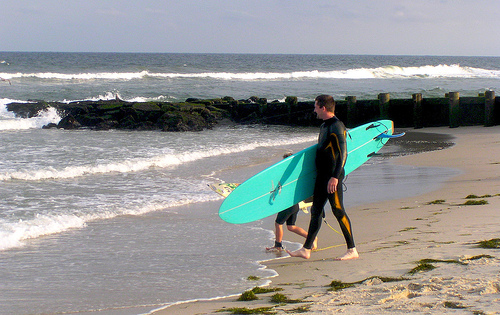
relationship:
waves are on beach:
[1, 66, 498, 258] [138, 124, 497, 314]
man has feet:
[287, 94, 360, 262] [285, 248, 360, 261]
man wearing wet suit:
[287, 94, 360, 262] [303, 117, 356, 251]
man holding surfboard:
[287, 94, 360, 262] [217, 119, 407, 226]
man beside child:
[287, 94, 360, 262] [267, 203, 319, 250]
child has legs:
[267, 203, 319, 250] [266, 225, 318, 255]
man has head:
[287, 94, 360, 262] [314, 94, 335, 121]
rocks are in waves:
[59, 100, 237, 133] [1, 66, 498, 258]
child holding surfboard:
[267, 203, 319, 250] [211, 180, 314, 213]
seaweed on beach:
[237, 191, 500, 315] [138, 124, 497, 314]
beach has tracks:
[138, 124, 497, 314] [375, 236, 460, 249]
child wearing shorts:
[267, 203, 319, 250] [274, 202, 297, 227]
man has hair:
[287, 94, 360, 262] [314, 95, 337, 113]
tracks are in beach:
[375, 236, 460, 249] [138, 124, 497, 314]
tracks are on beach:
[375, 236, 460, 249] [138, 124, 497, 314]